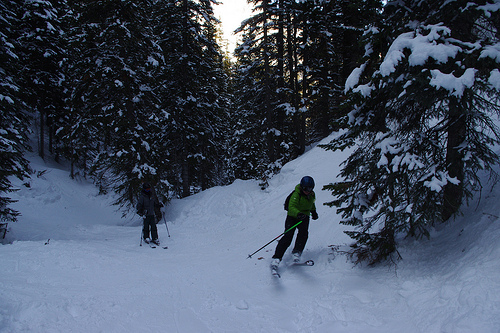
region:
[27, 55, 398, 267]
this is a mountain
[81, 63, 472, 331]
this is a forest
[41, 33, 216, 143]
the forest is snow covered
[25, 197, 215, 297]
the snow is white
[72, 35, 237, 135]
the trees are evergreen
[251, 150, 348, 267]
these are skiers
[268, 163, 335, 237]
the jacket is green and black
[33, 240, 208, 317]
area filled with white snow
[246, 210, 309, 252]
yellow ski pole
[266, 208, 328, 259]
long pair of black ski pants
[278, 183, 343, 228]
lime green ski jacket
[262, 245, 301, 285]
white and blue shoes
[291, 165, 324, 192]
shiny blue ski helmet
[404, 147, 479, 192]
snow on the tall tree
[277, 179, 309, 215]
black back pack on skier's back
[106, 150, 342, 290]
skiers skiing on the snow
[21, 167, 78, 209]
tracks in the white snow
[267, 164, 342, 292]
This is a person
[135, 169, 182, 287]
This is a person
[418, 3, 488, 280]
This is a tree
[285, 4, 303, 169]
This is a tree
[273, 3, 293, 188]
This is a tree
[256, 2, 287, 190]
This is a tree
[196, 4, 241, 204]
This is a tree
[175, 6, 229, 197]
This is a tree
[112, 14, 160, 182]
This is a tree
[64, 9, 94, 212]
This is a tree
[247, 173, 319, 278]
person holding a ski pole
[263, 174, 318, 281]
person on a pair of skis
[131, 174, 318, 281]
two people skiing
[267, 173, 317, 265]
person wearing a green coat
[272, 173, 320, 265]
person wearing black pants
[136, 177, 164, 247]
person wearing a dark gray coat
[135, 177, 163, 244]
person wearing black pants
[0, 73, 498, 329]
ground covered in snow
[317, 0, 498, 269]
snow on the branches of an evergreen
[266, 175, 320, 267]
person wearing a blue helmet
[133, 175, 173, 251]
a skier in a black outfit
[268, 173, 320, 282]
a skier in a green coat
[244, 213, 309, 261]
a blue ski pole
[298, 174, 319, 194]
a blue ski helmet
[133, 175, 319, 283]
two cross country skiers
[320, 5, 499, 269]
tall snow covered trees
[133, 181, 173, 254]
a skier holding ski poles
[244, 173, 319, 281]
a skier wearing a helmet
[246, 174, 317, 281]
a skier in a blue helmet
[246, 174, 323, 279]
a skier in the snow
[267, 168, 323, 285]
a person is skiing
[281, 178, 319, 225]
a person is wearing a green parka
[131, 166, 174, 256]
a person in black is skiing